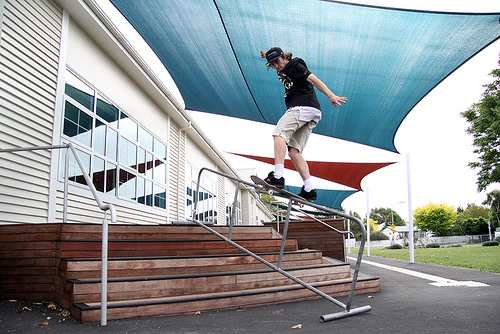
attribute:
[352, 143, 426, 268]
poles — white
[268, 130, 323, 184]
muscles — strength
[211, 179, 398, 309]
rails — assisting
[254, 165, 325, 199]
shoes — black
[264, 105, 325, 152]
pants — tan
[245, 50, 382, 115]
arms — balancing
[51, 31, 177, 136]
wall — white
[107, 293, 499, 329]
ground — paved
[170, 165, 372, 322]
rail — skateboarding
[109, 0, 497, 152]
canopy — blue, hung up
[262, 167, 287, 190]
sneaker — black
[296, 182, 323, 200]
sneaker — black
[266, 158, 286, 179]
sock — white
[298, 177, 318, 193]
sock — white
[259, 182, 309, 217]
wheels — white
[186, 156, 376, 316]
railing — metal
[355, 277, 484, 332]
ground — black